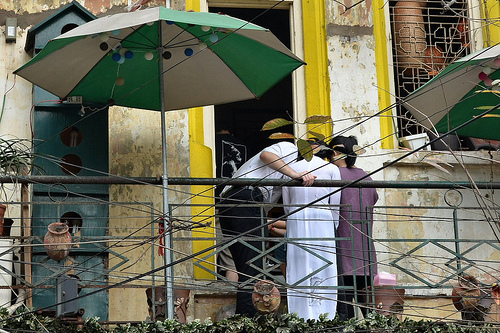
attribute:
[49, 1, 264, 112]
umbrella — open, partial, green, white, opened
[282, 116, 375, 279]
people — standing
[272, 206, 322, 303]
dress — long, white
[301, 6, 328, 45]
paint — white, yellow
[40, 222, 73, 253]
pot — balanced, standing, here, brown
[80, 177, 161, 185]
railing — balcony, metal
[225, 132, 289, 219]
man — bending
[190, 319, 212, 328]
leaves — brown, green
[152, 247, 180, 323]
pole — metal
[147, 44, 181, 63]
balls — small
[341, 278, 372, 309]
leggings — black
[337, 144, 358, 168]
hair — ponytail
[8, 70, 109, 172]
bird house — large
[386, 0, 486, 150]
window — large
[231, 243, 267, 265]
shorts — grey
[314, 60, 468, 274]
building — old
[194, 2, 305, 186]
door — high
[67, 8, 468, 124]
umbrellas — big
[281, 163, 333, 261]
robe — white